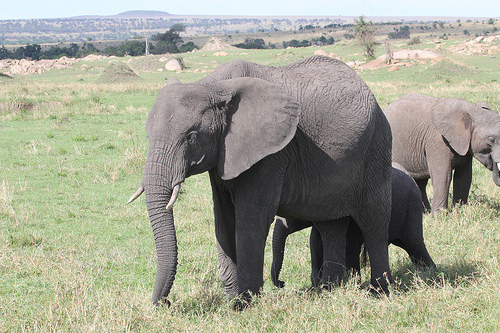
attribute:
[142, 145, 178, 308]
trunk — gray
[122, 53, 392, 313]
elephant — adult, walking, big, grey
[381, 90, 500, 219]
elephant — grey, facing away, eating, walking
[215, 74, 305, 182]
left ear — large, gray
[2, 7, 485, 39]
mountain range — large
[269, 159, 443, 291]
elephant — baby, small, young, walking, grey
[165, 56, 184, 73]
boulder — large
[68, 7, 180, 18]
hill — distant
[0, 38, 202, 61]
trees — green, distant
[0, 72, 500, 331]
grass — tan, green, here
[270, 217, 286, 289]
trunk — small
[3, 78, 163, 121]
grass — yellow, dry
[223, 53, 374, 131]
back — curved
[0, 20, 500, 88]
terrain — hilly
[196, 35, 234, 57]
mound — tan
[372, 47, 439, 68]
mound — tan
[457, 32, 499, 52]
mound — tan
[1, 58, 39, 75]
mound — tan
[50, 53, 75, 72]
mound — tan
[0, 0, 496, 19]
sky — pale blue, hazy